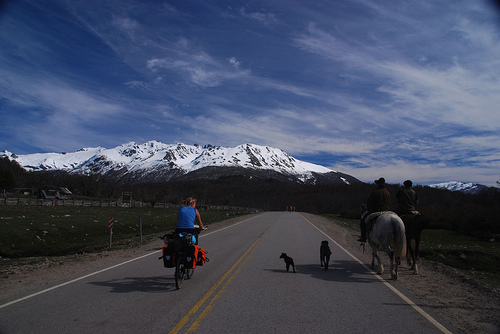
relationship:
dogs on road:
[265, 230, 334, 279] [232, 223, 318, 246]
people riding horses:
[368, 171, 416, 208] [371, 205, 432, 272]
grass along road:
[96, 211, 135, 231] [232, 223, 318, 246]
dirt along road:
[76, 249, 100, 266] [232, 223, 318, 246]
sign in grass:
[102, 219, 119, 233] [96, 211, 135, 231]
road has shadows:
[232, 223, 318, 246] [331, 258, 357, 282]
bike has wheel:
[166, 229, 216, 285] [159, 259, 192, 287]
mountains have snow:
[183, 144, 258, 176] [106, 152, 127, 164]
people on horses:
[368, 171, 416, 208] [371, 205, 432, 272]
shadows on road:
[331, 258, 357, 282] [232, 223, 318, 246]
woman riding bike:
[177, 193, 207, 236] [166, 229, 216, 285]